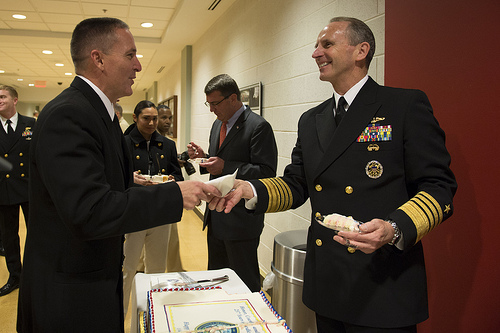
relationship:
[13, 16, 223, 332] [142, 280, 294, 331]
man speaking over cake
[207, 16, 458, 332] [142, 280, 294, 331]
man speaking over cake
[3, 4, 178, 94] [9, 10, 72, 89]
tiled ceiling with white lights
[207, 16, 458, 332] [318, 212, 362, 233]
man holding cake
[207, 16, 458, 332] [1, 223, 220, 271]
man standing on floor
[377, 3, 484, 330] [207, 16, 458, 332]
wall in back of man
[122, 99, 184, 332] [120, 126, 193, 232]
lady has jacket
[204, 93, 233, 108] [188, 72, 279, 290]
glasses being worn by man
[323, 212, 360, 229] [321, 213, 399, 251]
cake in hand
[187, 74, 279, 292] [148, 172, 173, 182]
man has cake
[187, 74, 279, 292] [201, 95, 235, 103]
man wearing glasses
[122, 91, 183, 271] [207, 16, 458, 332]
lady watching man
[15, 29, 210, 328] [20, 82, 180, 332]
man wearing black suit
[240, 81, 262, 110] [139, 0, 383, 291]
picture on wall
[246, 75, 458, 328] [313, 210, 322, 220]
jacket with button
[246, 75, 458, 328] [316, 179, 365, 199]
jacket with button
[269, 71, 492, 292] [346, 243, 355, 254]
jacket with button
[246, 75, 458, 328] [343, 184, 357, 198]
jacket with button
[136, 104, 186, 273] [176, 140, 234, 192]
man holding plates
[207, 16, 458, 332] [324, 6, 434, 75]
man with hair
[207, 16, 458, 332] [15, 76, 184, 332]
man in black suit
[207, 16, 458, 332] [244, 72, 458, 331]
man in uniform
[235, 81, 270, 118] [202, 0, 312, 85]
frame on wall